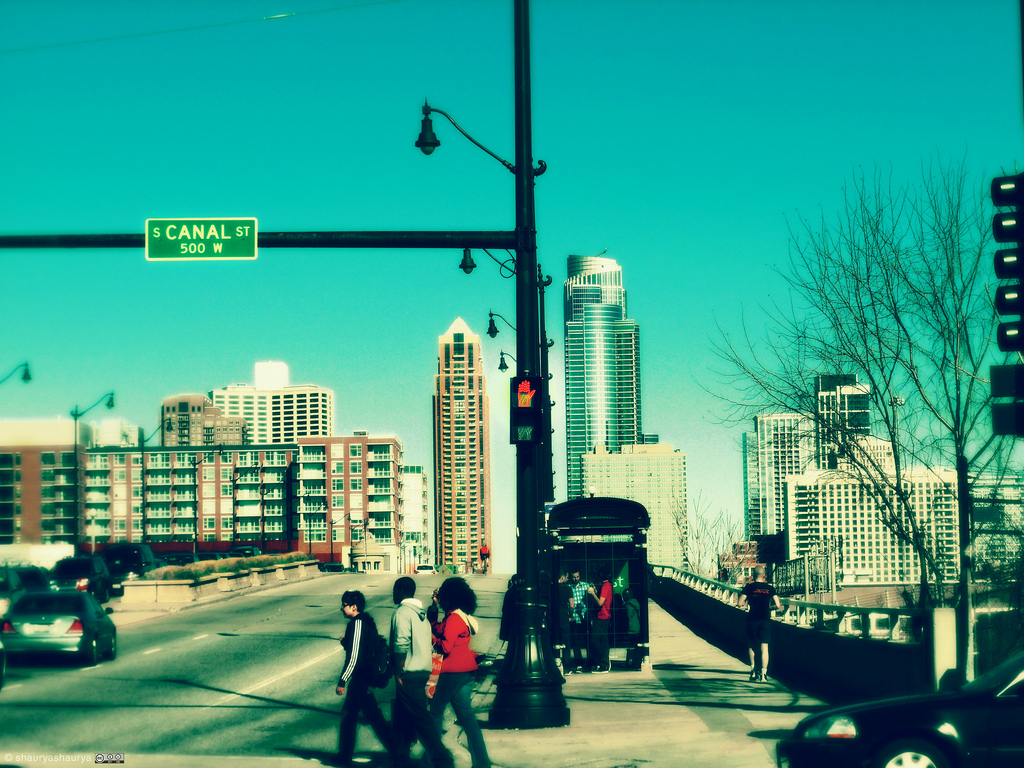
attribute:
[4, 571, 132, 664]
car — driving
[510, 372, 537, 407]
sign — for pedestrian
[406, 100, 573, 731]
street light — tall, black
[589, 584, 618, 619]
shirt — short sleeve, red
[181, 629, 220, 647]
street marking — white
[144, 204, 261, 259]
sign — white, green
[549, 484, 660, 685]
stop — bus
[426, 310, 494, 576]
building — tall, brown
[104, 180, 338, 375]
sign — green, white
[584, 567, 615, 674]
person — one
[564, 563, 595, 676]
person — one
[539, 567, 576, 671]
person — one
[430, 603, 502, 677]
coat — red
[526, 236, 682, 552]
building — tall, silver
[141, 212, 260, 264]
street sign — green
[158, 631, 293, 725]
lines — white